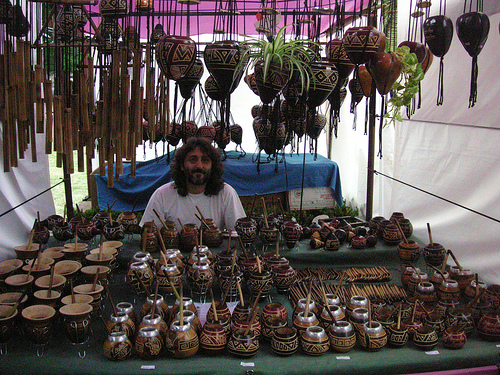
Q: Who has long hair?
A: The man.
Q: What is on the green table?
A: Pots.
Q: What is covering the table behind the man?
A: Blue blanket.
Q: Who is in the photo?
A: A man with a beard.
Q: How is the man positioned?
A: He is sitting.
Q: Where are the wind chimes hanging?
A: To the left of the man.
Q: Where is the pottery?
A: On the table.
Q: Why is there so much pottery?
A: The man sells pottery.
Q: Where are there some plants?
A: In some of the pottery.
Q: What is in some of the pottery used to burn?
A: Incense.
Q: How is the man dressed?
A: In a white T-shirt.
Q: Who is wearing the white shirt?
A: The man.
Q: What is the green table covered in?
A: Pots.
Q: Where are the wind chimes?
A: Hanging from the ceiling.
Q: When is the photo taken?
A: Daytime.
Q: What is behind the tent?
A: Grass.